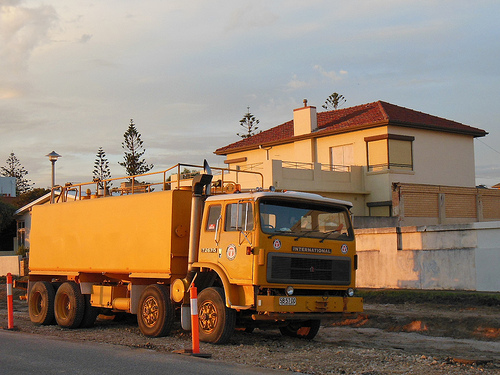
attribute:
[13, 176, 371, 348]
truck — yellow, parked, large, in the road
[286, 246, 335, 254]
writing — white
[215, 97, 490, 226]
house — red, white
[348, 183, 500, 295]
fence — off white, cement, made of cement, dirty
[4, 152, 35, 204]
tree — green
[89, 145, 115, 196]
tree — green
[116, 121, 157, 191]
tree — green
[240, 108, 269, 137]
tree — green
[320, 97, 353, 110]
tree — green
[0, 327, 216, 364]
road — paved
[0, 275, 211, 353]
pilons — orange, white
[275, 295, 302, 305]
license plate — white, black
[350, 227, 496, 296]
wall — white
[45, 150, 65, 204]
street light — in the distance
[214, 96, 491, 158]
roof — red, tile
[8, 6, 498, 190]
sky — cloudy, blue, grey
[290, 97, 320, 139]
chimney — red, white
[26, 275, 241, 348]
tires — black, yellow